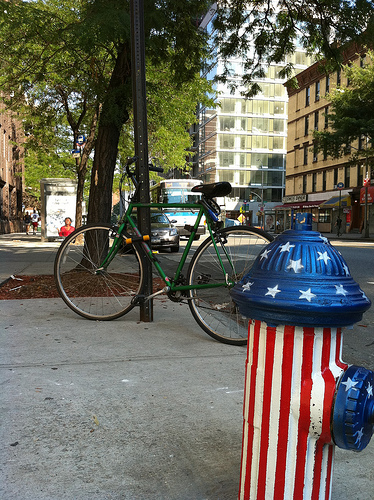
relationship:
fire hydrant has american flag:
[227, 212, 374, 499] [228, 212, 373, 499]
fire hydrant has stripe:
[227, 212, 374, 499] [273, 324, 296, 499]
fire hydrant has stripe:
[227, 212, 374, 499] [249, 322, 269, 499]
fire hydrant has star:
[227, 212, 374, 499] [297, 288, 317, 302]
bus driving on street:
[151, 178, 208, 241] [121, 236, 373, 373]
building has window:
[195, 0, 337, 225] [218, 134, 235, 150]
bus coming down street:
[151, 178, 208, 241] [121, 236, 373, 373]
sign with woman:
[44, 194, 77, 239] [57, 217, 75, 238]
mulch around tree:
[0, 273, 168, 300] [57, 0, 156, 275]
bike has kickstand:
[53, 153, 276, 346] [177, 293, 219, 302]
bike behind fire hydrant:
[53, 153, 276, 346] [227, 212, 374, 499]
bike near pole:
[53, 153, 276, 346] [128, 0, 153, 323]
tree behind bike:
[57, 0, 156, 275] [53, 153, 276, 346]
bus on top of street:
[151, 178, 208, 241] [121, 236, 373, 373]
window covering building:
[249, 135, 269, 150] [195, 0, 337, 225]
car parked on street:
[113, 212, 180, 257] [121, 236, 373, 373]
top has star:
[230, 212, 372, 327] [297, 288, 317, 302]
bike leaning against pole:
[53, 153, 276, 346] [128, 0, 153, 323]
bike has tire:
[53, 153, 276, 346] [52, 222, 146, 321]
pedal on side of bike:
[128, 293, 149, 307] [53, 153, 276, 346]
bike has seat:
[53, 153, 276, 346] [190, 180, 232, 196]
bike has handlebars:
[53, 153, 276, 346] [125, 153, 165, 174]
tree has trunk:
[57, 0, 156, 275] [80, 41, 131, 265]